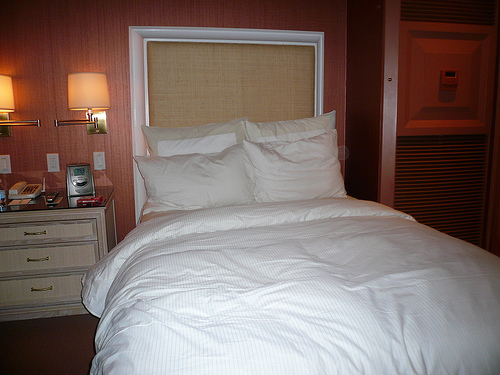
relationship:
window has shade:
[127, 24, 324, 224] [146, 43, 313, 126]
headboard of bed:
[139, 36, 314, 136] [117, 112, 491, 373]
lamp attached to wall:
[1, 71, 20, 127] [1, 1, 487, 246]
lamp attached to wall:
[61, 64, 117, 132] [1, 1, 487, 246]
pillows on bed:
[129, 107, 350, 216] [89, 155, 497, 374]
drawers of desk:
[0, 270, 88, 312] [0, 183, 120, 320]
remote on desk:
[44, 188, 59, 202] [0, 185, 118, 318]